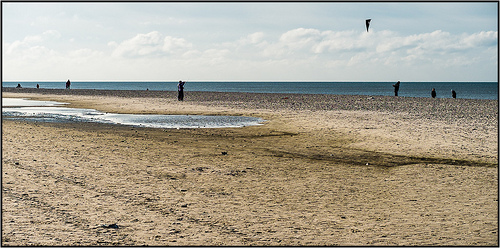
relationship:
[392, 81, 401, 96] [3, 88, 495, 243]
kite flyers at beach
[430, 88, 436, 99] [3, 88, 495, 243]
people at beach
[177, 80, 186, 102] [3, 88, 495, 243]
man at beach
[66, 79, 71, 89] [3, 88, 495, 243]
man at beach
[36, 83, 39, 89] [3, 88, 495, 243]
people at beach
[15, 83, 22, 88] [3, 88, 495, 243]
people at beach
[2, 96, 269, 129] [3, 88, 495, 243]
puddles on beach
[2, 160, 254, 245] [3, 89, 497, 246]
tire tracks in sand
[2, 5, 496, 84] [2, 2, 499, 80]
clouds in sky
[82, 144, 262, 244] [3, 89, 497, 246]
footprints in sand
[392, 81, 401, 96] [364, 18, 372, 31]
kite flyers flying kite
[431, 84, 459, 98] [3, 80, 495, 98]
people close to water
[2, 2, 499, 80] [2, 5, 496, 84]
sky with clouds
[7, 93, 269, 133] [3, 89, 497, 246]
puddles in sand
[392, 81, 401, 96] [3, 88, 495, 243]
kite flyers standing on beach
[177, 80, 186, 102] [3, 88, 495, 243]
man standing on beach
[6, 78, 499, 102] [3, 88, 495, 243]
water beyond beach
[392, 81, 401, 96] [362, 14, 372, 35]
kite flyers flying kite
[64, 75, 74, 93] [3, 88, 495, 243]
man standing on beach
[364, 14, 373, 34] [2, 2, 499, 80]
kite in sky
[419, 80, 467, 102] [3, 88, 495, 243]
bystanders on beach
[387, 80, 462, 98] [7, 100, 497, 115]
kite flyers on shore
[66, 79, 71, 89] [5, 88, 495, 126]
man walking on sand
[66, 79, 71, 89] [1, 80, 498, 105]
man by ocean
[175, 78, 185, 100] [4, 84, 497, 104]
man on beach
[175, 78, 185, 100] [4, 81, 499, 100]
man watching water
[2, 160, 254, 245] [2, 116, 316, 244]
tire tracks in sand